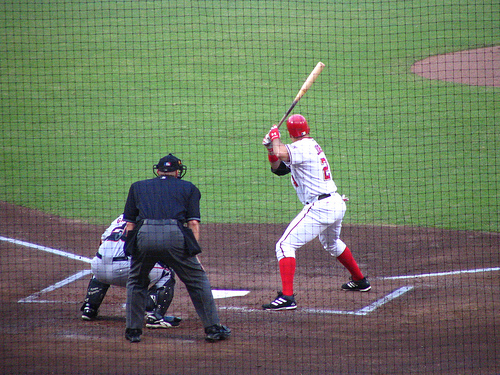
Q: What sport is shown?
A: Baseball.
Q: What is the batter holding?
A: Baseball bat.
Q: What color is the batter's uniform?
A: Red, white.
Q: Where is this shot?
A: Baseball park.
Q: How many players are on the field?
A: 2.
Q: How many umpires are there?
A: 1.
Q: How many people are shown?
A: 3.